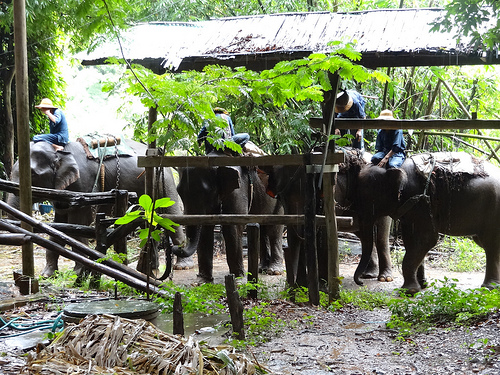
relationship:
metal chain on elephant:
[110, 141, 121, 201] [2, 140, 184, 278]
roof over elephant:
[81, 6, 496, 68] [334, 151, 496, 295]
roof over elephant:
[81, 6, 496, 68] [2, 140, 184, 278]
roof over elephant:
[81, 6, 496, 68] [162, 150, 284, 286]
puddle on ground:
[156, 308, 223, 333] [1, 225, 498, 370]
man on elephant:
[323, 87, 370, 150] [325, 141, 375, 282]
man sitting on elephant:
[33, 97, 69, 151] [4, 133, 198, 285]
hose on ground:
[7, 301, 67, 373] [4, 284, 475, 372]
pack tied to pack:
[75, 133, 131, 160] [409, 148, 481, 181]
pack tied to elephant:
[75, 133, 131, 160] [354, 167, 497, 297]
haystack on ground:
[22, 303, 272, 374] [2, 265, 377, 365]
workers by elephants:
[301, 70, 443, 203] [22, 118, 175, 288]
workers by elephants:
[301, 70, 443, 203] [167, 133, 287, 267]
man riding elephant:
[26, 97, 79, 165] [12, 132, 195, 278]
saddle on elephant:
[75, 130, 138, 160] [345, 140, 499, 297]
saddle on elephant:
[412, 148, 492, 186] [30, 127, 146, 191]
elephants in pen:
[163, 112, 479, 286] [144, 101, 469, 308]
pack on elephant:
[76, 131, 135, 162] [23, 123, 186, 263]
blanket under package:
[413, 157, 498, 176] [74, 126, 126, 150]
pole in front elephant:
[6, 15, 26, 259] [2, 140, 184, 278]